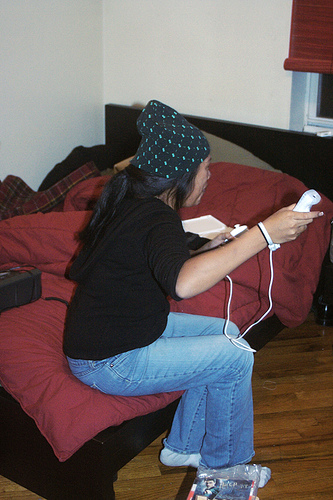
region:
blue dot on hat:
[154, 101, 158, 109]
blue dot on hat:
[147, 111, 152, 119]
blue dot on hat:
[161, 112, 168, 118]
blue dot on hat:
[171, 113, 176, 119]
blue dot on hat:
[172, 109, 178, 114]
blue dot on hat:
[136, 153, 139, 160]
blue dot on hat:
[136, 162, 142, 168]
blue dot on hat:
[146, 157, 151, 166]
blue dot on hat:
[154, 166, 159, 174]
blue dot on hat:
[164, 171, 170, 178]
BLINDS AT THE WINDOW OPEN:
[298, 23, 318, 69]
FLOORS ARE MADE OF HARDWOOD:
[302, 379, 323, 432]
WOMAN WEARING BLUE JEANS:
[174, 352, 218, 364]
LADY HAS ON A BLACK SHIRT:
[123, 274, 141, 310]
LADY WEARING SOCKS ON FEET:
[166, 452, 173, 462]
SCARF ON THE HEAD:
[133, 101, 204, 174]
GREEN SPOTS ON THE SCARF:
[175, 140, 185, 146]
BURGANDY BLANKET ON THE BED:
[19, 339, 41, 375]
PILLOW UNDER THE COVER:
[229, 150, 246, 162]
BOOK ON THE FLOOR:
[192, 478, 252, 498]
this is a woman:
[85, 109, 331, 472]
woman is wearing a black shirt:
[49, 161, 208, 366]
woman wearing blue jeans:
[61, 290, 268, 458]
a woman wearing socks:
[158, 439, 270, 496]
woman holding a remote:
[228, 167, 332, 362]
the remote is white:
[213, 151, 321, 366]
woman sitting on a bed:
[2, 94, 327, 478]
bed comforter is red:
[0, 151, 330, 454]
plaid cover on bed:
[5, 153, 94, 221]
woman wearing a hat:
[123, 103, 214, 186]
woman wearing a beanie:
[65, 79, 267, 262]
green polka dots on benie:
[144, 97, 195, 176]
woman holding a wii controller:
[76, 100, 321, 315]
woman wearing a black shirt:
[41, 173, 212, 378]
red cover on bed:
[19, 348, 109, 465]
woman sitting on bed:
[71, 96, 316, 491]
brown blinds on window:
[283, 8, 327, 130]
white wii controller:
[254, 159, 327, 266]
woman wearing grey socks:
[160, 434, 265, 497]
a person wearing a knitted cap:
[107, 105, 208, 196]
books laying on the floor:
[193, 463, 262, 490]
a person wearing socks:
[159, 440, 210, 466]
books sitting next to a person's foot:
[194, 461, 258, 497]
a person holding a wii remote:
[226, 192, 331, 218]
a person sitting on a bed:
[87, 149, 183, 377]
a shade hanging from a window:
[274, 29, 326, 92]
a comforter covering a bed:
[2, 193, 63, 258]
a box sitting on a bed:
[0, 254, 42, 337]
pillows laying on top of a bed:
[215, 134, 282, 186]